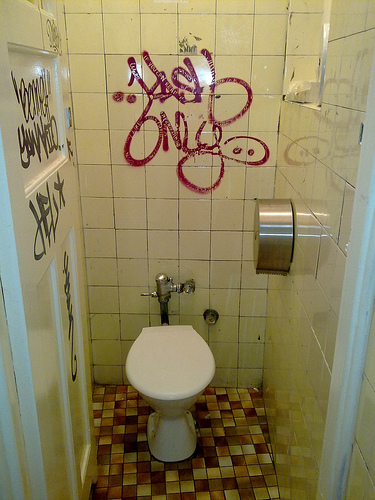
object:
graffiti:
[111, 33, 270, 197]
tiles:
[48, 1, 288, 389]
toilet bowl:
[124, 323, 215, 465]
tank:
[146, 405, 197, 464]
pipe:
[141, 272, 183, 326]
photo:
[0, 1, 375, 500]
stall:
[54, 0, 374, 500]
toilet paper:
[252, 200, 293, 275]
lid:
[124, 325, 216, 401]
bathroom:
[0, 0, 374, 498]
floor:
[90, 382, 284, 499]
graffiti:
[7, 0, 79, 388]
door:
[0, 0, 98, 500]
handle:
[140, 291, 159, 298]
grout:
[287, 78, 309, 101]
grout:
[97, 3, 131, 265]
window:
[281, 0, 331, 110]